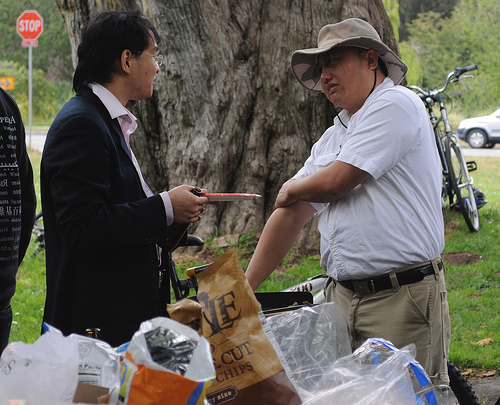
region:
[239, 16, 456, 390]
man in a white shirt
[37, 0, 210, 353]
man in a black suit jacket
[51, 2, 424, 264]
very large light brown and grey tree trunk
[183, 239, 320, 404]
brown bag of kettle cooked chips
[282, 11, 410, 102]
camouflaged sun hat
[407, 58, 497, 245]
silver and green bicycle leaned against a tree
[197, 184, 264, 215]
disposable red paper plate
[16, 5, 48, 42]
red and white octagonal stop sign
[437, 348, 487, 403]
part of a black rubber tire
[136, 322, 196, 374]
silver foiled inside of a chip bag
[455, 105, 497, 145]
a car on the street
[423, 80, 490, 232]
a bike next to the tree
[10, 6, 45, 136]
a stop sign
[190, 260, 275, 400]
a bag of chips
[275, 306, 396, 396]
a sack on the table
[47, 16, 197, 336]
a man in a suit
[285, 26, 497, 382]
a man in a white shirt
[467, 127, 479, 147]
a tire on the car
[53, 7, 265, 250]
man i sholding a plate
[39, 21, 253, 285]
man i sholding a plate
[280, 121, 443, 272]
the shirt is white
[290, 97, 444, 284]
the shirt is white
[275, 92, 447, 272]
the shirt is white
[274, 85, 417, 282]
the shirt is white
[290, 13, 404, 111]
head of a person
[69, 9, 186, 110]
head of a person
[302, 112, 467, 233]
arm of a person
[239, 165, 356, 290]
arm of a person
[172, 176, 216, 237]
hand of a person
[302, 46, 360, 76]
eye of a person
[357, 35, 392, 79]
ear of a person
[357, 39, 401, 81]
an ear of a person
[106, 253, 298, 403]
Open bags of chips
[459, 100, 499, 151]
Front end of a car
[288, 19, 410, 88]
A hat on a man's head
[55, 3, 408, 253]
A large trunk of a tree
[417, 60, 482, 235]
A bike parked against a tree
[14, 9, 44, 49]
A stop sign on the side of a road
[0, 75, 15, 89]
A street sign pointing one direction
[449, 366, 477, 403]
Tread on a bike tire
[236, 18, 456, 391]
A man in a white shirt